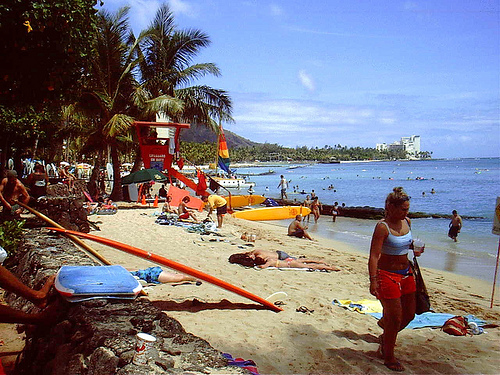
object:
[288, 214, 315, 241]
man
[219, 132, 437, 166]
bacground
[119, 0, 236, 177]
palm tree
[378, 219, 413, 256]
tank top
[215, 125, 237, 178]
flag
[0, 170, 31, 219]
man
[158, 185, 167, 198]
lifeguard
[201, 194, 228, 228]
person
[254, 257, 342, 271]
woman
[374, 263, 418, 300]
shorts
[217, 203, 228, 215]
shorts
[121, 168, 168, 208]
umbrella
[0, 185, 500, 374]
beach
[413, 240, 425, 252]
cup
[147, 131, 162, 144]
guard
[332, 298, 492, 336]
towel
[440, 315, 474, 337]
bag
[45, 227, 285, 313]
skis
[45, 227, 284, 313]
surfboard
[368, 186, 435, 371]
woman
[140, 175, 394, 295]
subathers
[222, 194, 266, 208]
surfboard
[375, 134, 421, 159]
building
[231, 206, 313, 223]
boards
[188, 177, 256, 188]
boat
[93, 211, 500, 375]
sand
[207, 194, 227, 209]
shirt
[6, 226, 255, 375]
ledge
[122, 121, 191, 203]
booth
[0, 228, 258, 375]
wall